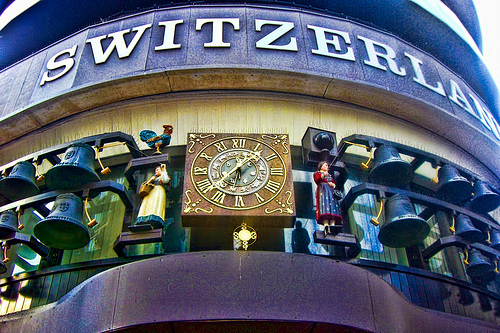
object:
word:
[37, 15, 498, 140]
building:
[0, 1, 500, 333]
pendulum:
[234, 223, 257, 251]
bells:
[34, 190, 95, 249]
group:
[0, 130, 104, 253]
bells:
[367, 144, 416, 186]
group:
[371, 130, 498, 250]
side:
[1, 2, 145, 333]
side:
[352, 2, 499, 332]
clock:
[180, 133, 297, 227]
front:
[112, 2, 384, 333]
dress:
[313, 171, 344, 221]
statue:
[313, 159, 342, 234]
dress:
[136, 170, 170, 226]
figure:
[132, 165, 173, 227]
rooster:
[138, 125, 174, 154]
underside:
[129, 85, 392, 147]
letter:
[255, 20, 299, 53]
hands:
[239, 151, 263, 167]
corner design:
[183, 130, 212, 151]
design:
[262, 133, 288, 155]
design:
[184, 191, 215, 215]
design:
[272, 199, 299, 229]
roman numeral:
[254, 143, 261, 151]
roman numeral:
[264, 153, 280, 162]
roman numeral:
[270, 167, 285, 176]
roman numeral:
[264, 178, 282, 194]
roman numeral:
[255, 191, 267, 204]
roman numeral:
[233, 195, 244, 208]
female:
[311, 160, 344, 235]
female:
[132, 163, 172, 231]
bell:
[44, 141, 100, 194]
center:
[221, 157, 258, 185]